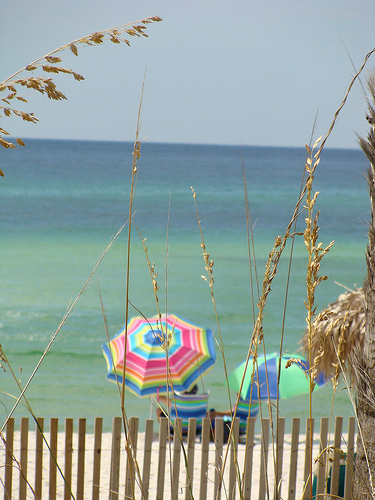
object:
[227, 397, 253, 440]
mane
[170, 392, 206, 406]
stripes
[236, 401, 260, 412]
stripes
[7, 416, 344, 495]
sandy beach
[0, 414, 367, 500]
fence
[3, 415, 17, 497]
slat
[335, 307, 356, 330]
dry leaf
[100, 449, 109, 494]
sand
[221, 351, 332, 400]
striped umbrella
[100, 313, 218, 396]
umbrellla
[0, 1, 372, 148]
blue sky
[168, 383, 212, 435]
chair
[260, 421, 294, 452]
sand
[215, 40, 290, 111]
clouds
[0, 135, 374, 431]
water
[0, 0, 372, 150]
sky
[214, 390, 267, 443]
chair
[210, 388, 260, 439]
person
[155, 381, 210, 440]
person